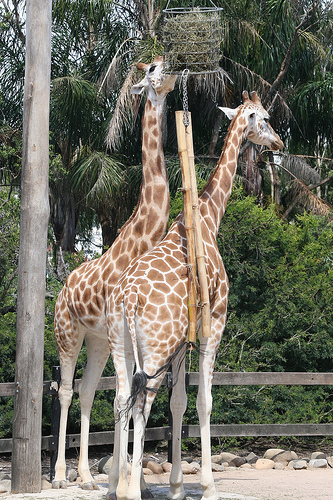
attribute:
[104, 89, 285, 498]
giraffe — patterned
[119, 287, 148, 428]
tail — long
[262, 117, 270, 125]
eye — black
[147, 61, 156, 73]
eye — round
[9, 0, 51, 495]
trunk — tall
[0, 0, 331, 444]
trees — green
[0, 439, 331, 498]
ground — light brown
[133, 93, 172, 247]
neck — long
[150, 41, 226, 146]
giraffe — eating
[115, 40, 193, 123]
giraffe — eating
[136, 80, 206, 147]
giraffe — eating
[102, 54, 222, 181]
giraffe — eating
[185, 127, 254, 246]
neck — long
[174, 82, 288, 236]
neck — long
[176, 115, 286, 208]
neck — long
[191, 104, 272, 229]
neck — long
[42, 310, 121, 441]
leg — long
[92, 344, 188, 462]
leg — long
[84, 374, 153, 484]
leg — long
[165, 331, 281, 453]
leg — long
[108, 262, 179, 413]
tail — long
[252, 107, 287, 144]
eye — black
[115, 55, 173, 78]
eye — black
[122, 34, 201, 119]
giraffe — eating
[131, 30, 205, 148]
giraffe — eating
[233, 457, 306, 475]
rocks — grey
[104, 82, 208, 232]
neck — long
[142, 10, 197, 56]
basket — full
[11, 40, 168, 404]
trunk — tall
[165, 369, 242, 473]
leg — long